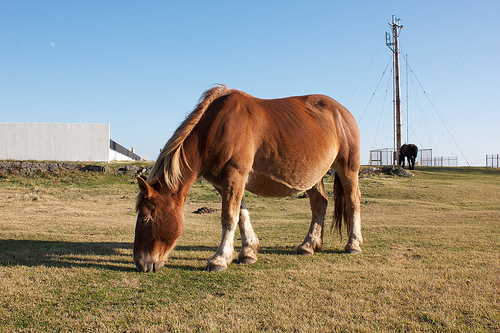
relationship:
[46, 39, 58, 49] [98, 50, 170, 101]
moon in sky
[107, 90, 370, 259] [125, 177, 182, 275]
horse has a head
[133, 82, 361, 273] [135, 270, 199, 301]
horse eating grass